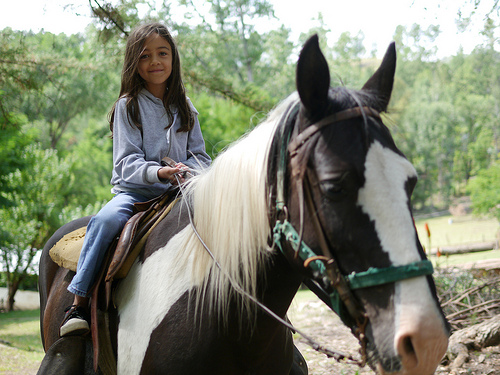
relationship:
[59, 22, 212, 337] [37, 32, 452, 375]
child on horse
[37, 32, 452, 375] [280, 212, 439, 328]
horse has bridle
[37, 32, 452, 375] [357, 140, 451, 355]
horse has stripe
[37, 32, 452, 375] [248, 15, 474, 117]
horse has two ears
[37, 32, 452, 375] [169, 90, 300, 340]
horse has blond mane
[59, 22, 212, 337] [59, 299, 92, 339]
child wearing shoes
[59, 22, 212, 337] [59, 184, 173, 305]
child wearing pants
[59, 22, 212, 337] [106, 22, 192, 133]
child has hair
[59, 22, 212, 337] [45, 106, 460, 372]
child riding horse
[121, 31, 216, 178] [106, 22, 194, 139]
child has brown hair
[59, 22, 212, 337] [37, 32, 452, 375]
child sitting on horse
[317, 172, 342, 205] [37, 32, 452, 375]
eye of a horse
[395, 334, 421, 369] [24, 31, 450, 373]
nostril of a horse's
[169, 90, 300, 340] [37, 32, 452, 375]
blond mane of a horse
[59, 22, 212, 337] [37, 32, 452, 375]
child sits on horse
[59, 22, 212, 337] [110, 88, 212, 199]
child has gray jacket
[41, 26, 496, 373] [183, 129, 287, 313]
horse has blond mane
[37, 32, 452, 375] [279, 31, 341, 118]
horse has ears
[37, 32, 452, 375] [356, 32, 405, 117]
horse has ears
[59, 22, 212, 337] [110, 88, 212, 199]
child wearing gray jacket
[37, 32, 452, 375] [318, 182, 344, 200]
horse has eye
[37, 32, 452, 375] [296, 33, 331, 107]
horse has ears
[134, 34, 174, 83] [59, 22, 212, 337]
face of child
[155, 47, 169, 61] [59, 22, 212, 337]
eye of child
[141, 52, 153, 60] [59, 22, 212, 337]
eye of child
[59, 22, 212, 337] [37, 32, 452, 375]
child riding horse